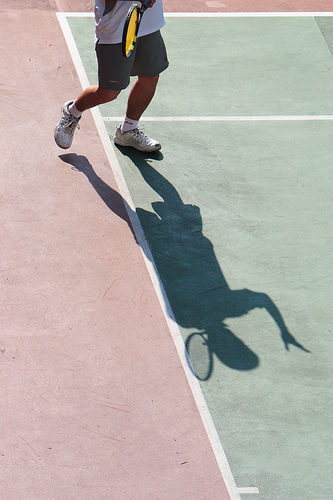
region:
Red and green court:
[38, 298, 312, 497]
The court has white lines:
[131, 298, 271, 492]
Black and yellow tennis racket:
[118, 1, 166, 62]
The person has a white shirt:
[85, 2, 199, 57]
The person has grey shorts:
[90, 23, 187, 93]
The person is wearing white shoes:
[44, 91, 183, 164]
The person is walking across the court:
[39, 0, 184, 160]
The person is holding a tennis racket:
[51, 3, 202, 167]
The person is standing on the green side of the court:
[55, 1, 208, 164]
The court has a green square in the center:
[122, 15, 327, 347]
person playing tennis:
[49, 0, 191, 159]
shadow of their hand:
[277, 328, 313, 357]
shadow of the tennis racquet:
[181, 329, 216, 381]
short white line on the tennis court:
[235, 480, 265, 495]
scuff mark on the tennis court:
[101, 399, 134, 416]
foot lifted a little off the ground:
[50, 91, 86, 151]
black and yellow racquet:
[119, 4, 146, 57]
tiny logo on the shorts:
[107, 74, 120, 85]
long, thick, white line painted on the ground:
[142, 246, 254, 499]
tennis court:
[53, 7, 330, 499]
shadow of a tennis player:
[51, 143, 310, 395]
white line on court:
[169, 380, 248, 477]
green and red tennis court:
[12, 174, 327, 495]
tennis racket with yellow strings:
[117, 0, 164, 64]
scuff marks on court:
[71, 365, 147, 446]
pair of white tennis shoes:
[42, 101, 180, 170]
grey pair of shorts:
[77, 31, 188, 91]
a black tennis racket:
[121, 0, 179, 54]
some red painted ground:
[23, 379, 172, 487]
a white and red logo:
[103, 78, 126, 87]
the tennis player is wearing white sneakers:
[50, 96, 83, 153]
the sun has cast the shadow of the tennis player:
[50, 130, 319, 382]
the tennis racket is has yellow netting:
[111, 1, 165, 62]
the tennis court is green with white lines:
[57, 11, 325, 493]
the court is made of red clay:
[1, 2, 217, 497]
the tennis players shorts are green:
[91, 10, 176, 96]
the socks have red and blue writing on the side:
[122, 117, 140, 131]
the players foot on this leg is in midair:
[49, 36, 127, 147]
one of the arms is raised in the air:
[225, 283, 312, 360]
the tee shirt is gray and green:
[94, 1, 171, 49]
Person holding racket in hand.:
[110, 11, 181, 80]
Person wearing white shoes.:
[54, 114, 196, 172]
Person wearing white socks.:
[49, 92, 192, 158]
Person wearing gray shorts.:
[97, 51, 175, 76]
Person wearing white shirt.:
[94, 7, 148, 47]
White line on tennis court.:
[181, 411, 253, 496]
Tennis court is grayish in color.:
[234, 396, 311, 490]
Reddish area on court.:
[31, 364, 126, 483]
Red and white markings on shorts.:
[100, 77, 122, 88]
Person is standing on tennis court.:
[40, 64, 234, 161]